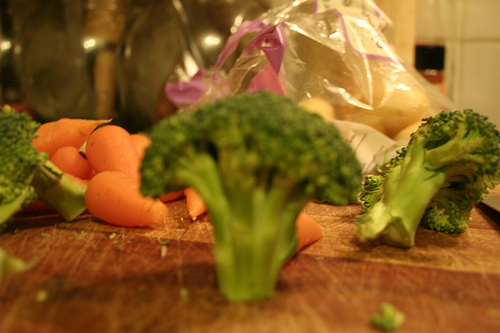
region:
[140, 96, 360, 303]
a single piece of brocole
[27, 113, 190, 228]
a couple piece of carrots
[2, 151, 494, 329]
a brown cutting board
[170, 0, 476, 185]
a plastic see through bag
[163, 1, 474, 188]
a bag with potatoes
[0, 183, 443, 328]
knife marks on a wooden cutting board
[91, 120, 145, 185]
an orange baby carrot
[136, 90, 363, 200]
the top of a piece of brocole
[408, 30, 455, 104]
a bottle of sauce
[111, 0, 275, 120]
a silver mixing bowl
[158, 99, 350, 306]
a piece of broccoli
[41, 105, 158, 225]
many carrots are kept in the table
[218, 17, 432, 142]
some packed vegetable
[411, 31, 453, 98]
entrance of the room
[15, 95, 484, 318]
orange and green coloured vegetables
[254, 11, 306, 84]
cover used to pack the vegetables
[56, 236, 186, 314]
a brown colour table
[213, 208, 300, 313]
stem of the broccoli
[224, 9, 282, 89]
pink colour cover edges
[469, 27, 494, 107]
white color tiles of the wall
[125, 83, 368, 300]
The broccoli is standing upright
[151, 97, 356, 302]
The broccoli is green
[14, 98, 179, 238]
The carrots are orange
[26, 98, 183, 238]
A pile of carrots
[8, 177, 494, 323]
The board is brown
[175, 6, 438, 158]
A purple and clear bag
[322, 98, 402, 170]
White label on the bag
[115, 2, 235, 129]
The bowl is silver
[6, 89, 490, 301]
Vegetables on a cutting board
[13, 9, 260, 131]
Bowls next to the cutting board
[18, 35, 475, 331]
vegetables on a cutting broad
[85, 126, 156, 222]
orange carrots on a broad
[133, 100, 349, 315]
broccili on a cutting broad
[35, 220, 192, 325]
a wooden cutting broad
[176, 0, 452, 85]
a plastic bag on a broad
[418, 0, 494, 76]
ref on back wall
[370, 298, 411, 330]
little pieces of vegetable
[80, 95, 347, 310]
carrot and broccilli ona broad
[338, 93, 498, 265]
broccilli lying on its side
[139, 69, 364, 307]
broccilli standing up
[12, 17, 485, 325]
vegetables on wooden cutting board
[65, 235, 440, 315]
knife marks made on board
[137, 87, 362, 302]
piece of broccoli standing upright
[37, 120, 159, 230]
round and stubby carrots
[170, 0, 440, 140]
purple and clear plastic bag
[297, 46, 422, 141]
round white produce in bag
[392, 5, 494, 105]
refrigerator doors with dark panel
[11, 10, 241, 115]
metal bowls behind vegetables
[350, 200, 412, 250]
angled cut in stem turning brown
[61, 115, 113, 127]
pointy end of a carrot